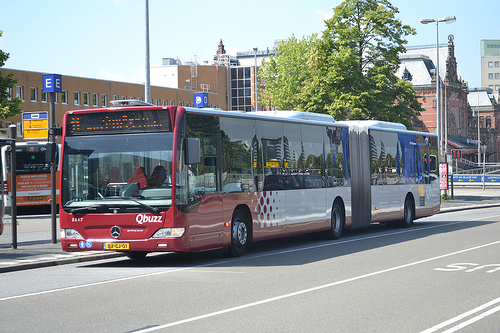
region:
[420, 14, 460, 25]
double street lights on pole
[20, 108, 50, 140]
blue and yellow sign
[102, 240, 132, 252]
yellow tag on bus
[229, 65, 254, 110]
vertacle bank of windows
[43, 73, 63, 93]
blue and white square sign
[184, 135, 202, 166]
mirror on side of bus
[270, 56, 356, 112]
green foliage on trees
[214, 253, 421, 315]
white stripes on road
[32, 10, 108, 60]
clear blue sky overhead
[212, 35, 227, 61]
top of skyscraper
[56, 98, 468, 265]
bus on the street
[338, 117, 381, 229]
connecting piece for bus parts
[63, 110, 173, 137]
area for bus route and number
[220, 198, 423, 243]
wheels on side of bus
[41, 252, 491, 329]
street for vehicles to travel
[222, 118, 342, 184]
window on the bus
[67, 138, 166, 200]
front window on the bus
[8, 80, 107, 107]
windows on a building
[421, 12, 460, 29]
lights on the street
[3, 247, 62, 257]
sidewalk near the bus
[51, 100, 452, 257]
double bus with red front and folding connection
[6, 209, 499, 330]
gray concrete city street with white lines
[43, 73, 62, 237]
pole with blue E cube sign attached to pole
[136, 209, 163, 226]
white words qbuzz on front of bus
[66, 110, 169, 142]
black digitel display with orange information on front of bus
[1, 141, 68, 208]
back of orange and white bus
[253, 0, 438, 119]
two large green trees seen behind bus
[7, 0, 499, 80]
clear blue sunny sky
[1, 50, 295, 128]
beige brick building near bus stop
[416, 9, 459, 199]
white pole with two lights on top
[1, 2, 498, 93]
blue of daytime sky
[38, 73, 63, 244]
blue cube on pole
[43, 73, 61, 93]
white letter on cube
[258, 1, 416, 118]
green leaves on tree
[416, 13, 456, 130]
two lights on tree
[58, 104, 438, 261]
side of long bus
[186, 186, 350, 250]
red and white design on bus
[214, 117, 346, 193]
reflection on bus window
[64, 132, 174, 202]
windshield on front of bus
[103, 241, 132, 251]
black and yellow license plate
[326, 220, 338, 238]
part of a wheel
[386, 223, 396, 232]
part of a road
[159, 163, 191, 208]
edge of a bus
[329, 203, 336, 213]
part of a wheel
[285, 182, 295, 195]
edge of a bus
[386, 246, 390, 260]
part of a road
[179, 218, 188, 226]
edge of a bus